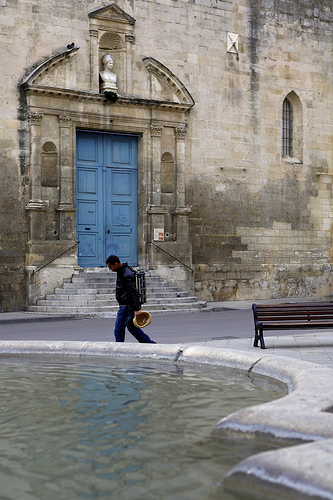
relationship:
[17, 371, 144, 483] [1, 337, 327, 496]
water in fountain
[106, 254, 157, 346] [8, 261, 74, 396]
man walking on sidewalk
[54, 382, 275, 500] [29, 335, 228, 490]
small body of water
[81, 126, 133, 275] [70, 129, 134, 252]
tall blue doors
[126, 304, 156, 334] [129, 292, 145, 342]
hat in hand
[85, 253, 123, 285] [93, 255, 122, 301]
hair on head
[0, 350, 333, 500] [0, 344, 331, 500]
water in fountain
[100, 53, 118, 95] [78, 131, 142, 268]
statue above door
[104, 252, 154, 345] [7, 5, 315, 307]
man walking by building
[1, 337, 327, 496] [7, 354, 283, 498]
fountain filled with water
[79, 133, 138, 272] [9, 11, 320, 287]
doors to building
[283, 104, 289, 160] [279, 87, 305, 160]
bars to window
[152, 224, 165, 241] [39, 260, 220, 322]
sign by steps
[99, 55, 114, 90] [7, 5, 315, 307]
decoration on building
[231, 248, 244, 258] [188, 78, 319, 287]
stone in wall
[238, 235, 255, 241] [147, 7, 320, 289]
stone in wall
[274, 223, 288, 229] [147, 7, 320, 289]
stone in wall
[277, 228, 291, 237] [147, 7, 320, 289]
stone in wall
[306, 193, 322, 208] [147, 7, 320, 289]
stone in wall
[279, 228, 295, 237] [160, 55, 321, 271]
stone in wall